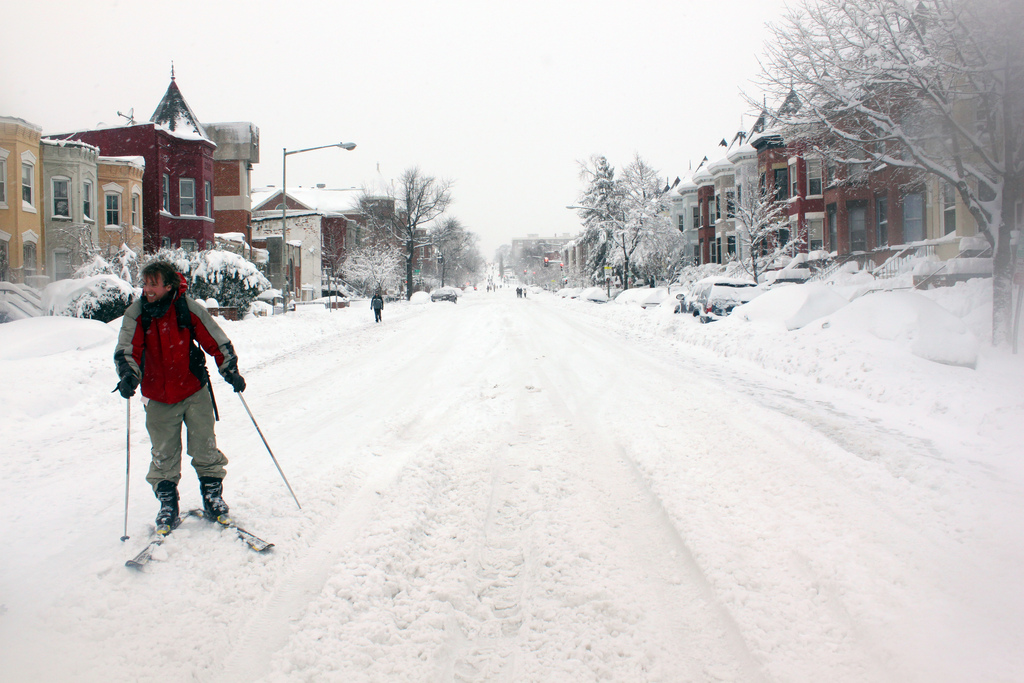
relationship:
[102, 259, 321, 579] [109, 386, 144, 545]
man holding ski pole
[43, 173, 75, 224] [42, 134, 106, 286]
window on building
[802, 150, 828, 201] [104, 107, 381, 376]
window on building